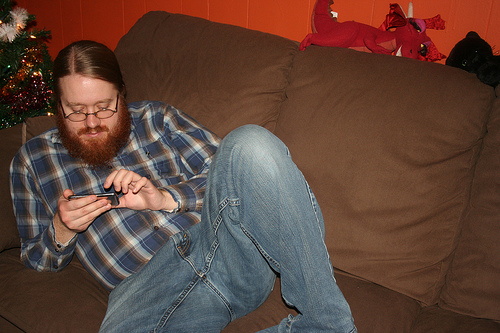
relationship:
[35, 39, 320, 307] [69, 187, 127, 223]
man with cell phone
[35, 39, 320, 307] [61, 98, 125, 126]
man wearing glasses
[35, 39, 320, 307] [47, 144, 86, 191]
man wearing shirt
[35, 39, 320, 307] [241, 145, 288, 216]
man wearing jeans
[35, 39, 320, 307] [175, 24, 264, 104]
man on sofa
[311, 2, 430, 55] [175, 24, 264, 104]
toy behind sofa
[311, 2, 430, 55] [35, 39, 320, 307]
toy above man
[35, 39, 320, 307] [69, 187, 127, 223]
man playing with cell phone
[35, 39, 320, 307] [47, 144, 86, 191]
man in shirt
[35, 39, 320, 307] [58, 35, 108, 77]
man has red hair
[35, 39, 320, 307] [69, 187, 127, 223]
man on cell phone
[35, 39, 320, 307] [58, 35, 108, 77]
man red hair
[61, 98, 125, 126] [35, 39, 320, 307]
glasses on man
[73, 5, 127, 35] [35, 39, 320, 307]
wall above man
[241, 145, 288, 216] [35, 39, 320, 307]
jeans on man